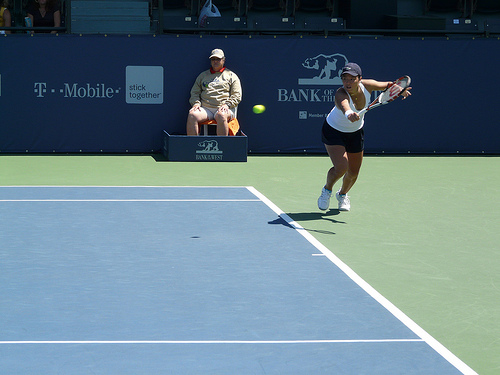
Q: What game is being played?
A: Tennis.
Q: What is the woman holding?
A: A tennis racket.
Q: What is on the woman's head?
A: Blue cap.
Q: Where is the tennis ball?
A: In the air.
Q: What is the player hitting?
A: Tennis ball.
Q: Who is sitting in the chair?
A: Spectator.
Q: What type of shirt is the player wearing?
A: White tank top.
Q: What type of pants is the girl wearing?
A: Black Shorts.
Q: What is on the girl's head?
A: Hat.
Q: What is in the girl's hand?
A: Tennis racket.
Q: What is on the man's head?
A: Hat.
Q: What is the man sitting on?
A: A chair.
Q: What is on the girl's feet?
A: Sneakers.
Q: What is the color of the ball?
A: Green.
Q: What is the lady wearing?
A: Sneakers.